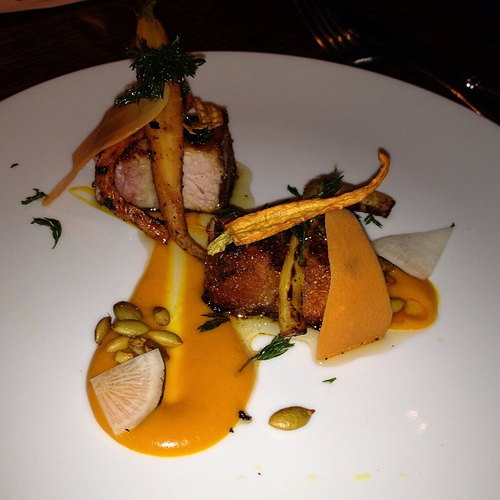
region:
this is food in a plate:
[13, 45, 440, 459]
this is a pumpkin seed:
[267, 392, 322, 441]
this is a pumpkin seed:
[149, 323, 188, 353]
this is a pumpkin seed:
[145, 295, 177, 329]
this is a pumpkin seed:
[111, 293, 153, 330]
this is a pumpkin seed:
[83, 310, 114, 340]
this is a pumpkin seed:
[109, 333, 134, 356]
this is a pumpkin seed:
[110, 317, 148, 337]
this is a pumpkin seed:
[110, 345, 140, 367]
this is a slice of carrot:
[134, 70, 219, 281]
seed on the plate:
[93, 313, 110, 343]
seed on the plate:
[270, 405, 317, 429]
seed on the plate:
[153, 325, 185, 347]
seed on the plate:
[111, 296, 144, 316]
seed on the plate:
[148, 307, 172, 323]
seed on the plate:
[115, 318, 150, 333]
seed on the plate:
[104, 335, 134, 349]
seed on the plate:
[385, 290, 407, 310]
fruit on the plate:
[88, 349, 166, 449]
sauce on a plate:
[70, 260, 260, 455]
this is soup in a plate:
[59, 270, 276, 453]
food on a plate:
[3, 4, 493, 499]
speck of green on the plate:
[319, 371, 341, 384]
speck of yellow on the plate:
[351, 470, 368, 485]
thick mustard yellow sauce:
[88, 240, 253, 465]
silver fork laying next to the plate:
[305, 11, 496, 143]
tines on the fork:
[297, 8, 374, 68]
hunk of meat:
[101, 100, 240, 225]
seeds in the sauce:
[85, 298, 187, 365]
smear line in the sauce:
[160, 249, 189, 401]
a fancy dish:
[2, 2, 494, 499]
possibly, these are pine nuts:
[91, 298, 195, 364]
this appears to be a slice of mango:
[313, 198, 393, 375]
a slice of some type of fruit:
[71, 340, 182, 432]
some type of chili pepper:
[201, 144, 411, 256]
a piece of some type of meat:
[104, 98, 248, 235]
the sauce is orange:
[146, 252, 238, 442]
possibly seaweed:
[121, 29, 218, 114]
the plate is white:
[36, 117, 407, 484]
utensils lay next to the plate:
[287, 25, 487, 119]